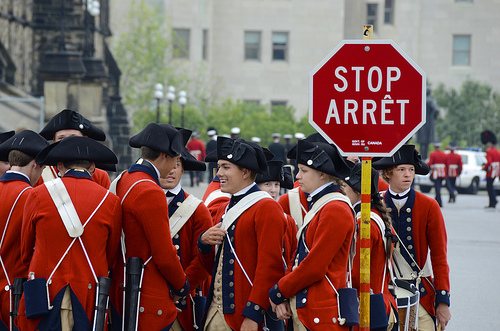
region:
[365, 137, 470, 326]
this is a person in uniform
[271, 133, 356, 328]
this is a person in uniform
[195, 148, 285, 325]
this is a person in uniform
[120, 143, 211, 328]
this is a person in uniform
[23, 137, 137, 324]
this is a person in uniform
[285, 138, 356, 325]
Person wearing a red jacket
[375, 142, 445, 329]
Person wearing a red jacket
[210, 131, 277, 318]
Person wearing a red jacket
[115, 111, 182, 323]
Person wearing a red jacket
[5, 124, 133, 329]
Person wearing a red jacket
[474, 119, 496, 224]
Person wearing a red jacket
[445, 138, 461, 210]
Person wearing a red jacket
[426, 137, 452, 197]
Person wearing a red jacket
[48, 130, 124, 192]
Black hat on head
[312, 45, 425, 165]
red and white stop sign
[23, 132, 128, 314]
man in red and white uniform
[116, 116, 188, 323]
man in red and white uniform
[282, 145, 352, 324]
man in red and white uniform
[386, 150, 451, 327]
man in red and white uniform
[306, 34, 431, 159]
red and white sign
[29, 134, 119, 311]
man in uniform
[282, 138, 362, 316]
man in uniform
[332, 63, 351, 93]
white letter on sign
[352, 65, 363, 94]
white letter on sign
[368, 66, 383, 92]
white letter on sign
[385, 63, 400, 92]
white letter on sign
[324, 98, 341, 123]
white letter on sign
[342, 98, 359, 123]
white letter on sign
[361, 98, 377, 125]
white letter on sign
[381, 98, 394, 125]
white letter on sign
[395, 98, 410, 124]
white letter on sign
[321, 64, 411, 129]
white letters on sign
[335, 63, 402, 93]
the word stop on a sign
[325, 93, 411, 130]
the word arret on a sign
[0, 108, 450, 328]
men in british military uniform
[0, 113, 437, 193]
blue berret hats on a group of men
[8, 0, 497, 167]
a beige building with windows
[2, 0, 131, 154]
a black iron fire escape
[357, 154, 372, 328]
a yellow pole with red stripes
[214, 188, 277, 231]
a white shoulder strap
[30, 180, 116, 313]
white criss crosses on the back of a jacket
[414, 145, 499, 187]
a white car driving past soldiers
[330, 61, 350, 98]
White letter on red sign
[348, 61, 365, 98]
White letter on red sign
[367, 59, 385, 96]
White letter on red sign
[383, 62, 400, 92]
White letter on red sign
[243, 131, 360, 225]
head of a girl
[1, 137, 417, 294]
many people wearing uniforms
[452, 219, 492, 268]
street next to people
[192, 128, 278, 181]
hat on person's head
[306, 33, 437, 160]
A red stop sign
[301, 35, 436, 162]
The red stop sign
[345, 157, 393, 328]
A yellow pole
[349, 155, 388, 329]
The yellow pole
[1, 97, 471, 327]
A group of soldiers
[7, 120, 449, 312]
The group of soldiers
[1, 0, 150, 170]
The building to the left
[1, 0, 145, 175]
A building to the left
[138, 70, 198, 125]
The trio of street lights